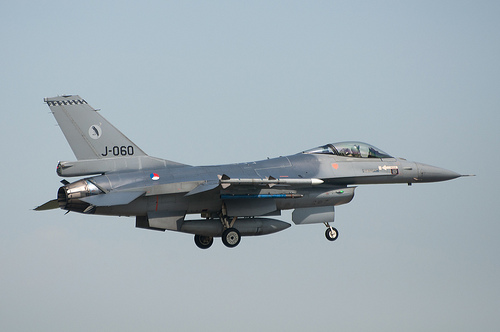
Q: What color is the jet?
A: Grey.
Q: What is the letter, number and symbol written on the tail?
A: J-060.